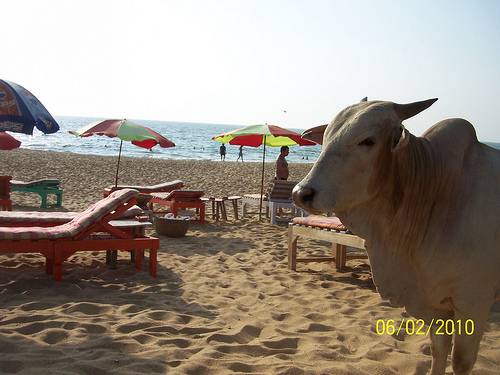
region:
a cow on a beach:
[282, 90, 496, 374]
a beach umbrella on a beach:
[211, 119, 313, 222]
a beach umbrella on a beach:
[68, 114, 180, 209]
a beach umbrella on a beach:
[0, 75, 58, 186]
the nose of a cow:
[286, 178, 317, 216]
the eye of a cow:
[358, 127, 379, 154]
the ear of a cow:
[375, 134, 412, 211]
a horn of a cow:
[392, 89, 439, 126]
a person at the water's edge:
[215, 137, 231, 164]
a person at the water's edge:
[232, 141, 249, 166]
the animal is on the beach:
[271, 20, 498, 373]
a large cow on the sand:
[268, 72, 498, 374]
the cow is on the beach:
[255, 55, 493, 373]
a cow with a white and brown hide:
[275, 72, 497, 374]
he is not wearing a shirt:
[262, 135, 309, 189]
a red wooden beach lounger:
[7, 178, 183, 287]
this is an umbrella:
[70, 105, 179, 272]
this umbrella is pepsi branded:
[0, 76, 67, 143]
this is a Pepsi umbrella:
[0, 77, 60, 142]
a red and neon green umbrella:
[201, 100, 328, 163]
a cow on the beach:
[283, 79, 499, 324]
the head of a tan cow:
[285, 92, 437, 248]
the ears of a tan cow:
[281, 109, 463, 134]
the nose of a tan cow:
[269, 175, 338, 205]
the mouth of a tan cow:
[300, 184, 342, 220]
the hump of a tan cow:
[420, 94, 482, 175]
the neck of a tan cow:
[328, 173, 422, 254]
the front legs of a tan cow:
[416, 289, 482, 373]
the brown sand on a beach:
[209, 263, 289, 345]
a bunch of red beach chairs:
[21, 179, 177, 266]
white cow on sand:
[283, 90, 493, 341]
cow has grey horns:
[301, 85, 428, 152]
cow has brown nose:
[286, 178, 327, 225]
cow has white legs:
[401, 310, 479, 372]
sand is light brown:
[163, 240, 245, 368]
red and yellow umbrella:
[215, 96, 290, 140]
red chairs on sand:
[112, 169, 218, 213]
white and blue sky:
[133, 17, 258, 107]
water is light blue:
[155, 128, 235, 163]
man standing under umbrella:
[260, 145, 299, 199]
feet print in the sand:
[129, 314, 266, 369]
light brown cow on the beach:
[299, 98, 491, 296]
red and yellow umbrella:
[216, 120, 303, 147]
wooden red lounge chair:
[3, 227, 156, 265]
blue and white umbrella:
[0, 78, 55, 140]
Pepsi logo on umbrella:
[21, 87, 36, 107]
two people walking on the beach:
[218, 142, 246, 162]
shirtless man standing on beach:
[275, 147, 291, 175]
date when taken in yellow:
[368, 313, 480, 345]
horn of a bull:
[384, 98, 439, 121]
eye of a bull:
[350, 131, 375, 149]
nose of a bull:
[290, 182, 317, 207]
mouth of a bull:
[306, 197, 355, 231]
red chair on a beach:
[1, 191, 161, 268]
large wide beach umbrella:
[0, 76, 65, 143]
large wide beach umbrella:
[68, 113, 183, 157]